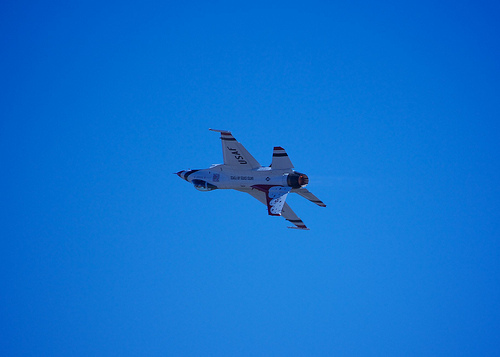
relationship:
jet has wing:
[173, 128, 327, 231] [207, 117, 268, 179]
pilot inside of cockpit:
[198, 177, 205, 193] [192, 172, 217, 198]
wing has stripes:
[207, 117, 268, 179] [206, 114, 247, 150]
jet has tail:
[161, 102, 335, 252] [267, 135, 338, 217]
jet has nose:
[161, 102, 335, 252] [152, 159, 196, 191]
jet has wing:
[161, 102, 335, 252] [207, 117, 268, 179]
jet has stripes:
[161, 102, 335, 252] [206, 114, 247, 150]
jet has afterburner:
[161, 102, 335, 252] [285, 155, 310, 191]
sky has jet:
[184, 27, 271, 74] [161, 102, 335, 252]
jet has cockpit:
[161, 102, 335, 252] [192, 172, 217, 198]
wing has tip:
[207, 117, 268, 179] [219, 128, 233, 139]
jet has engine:
[161, 102, 335, 252] [290, 177, 300, 195]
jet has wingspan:
[161, 102, 335, 252] [210, 110, 267, 251]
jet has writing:
[161, 102, 335, 252] [230, 167, 261, 187]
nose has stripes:
[152, 159, 196, 191] [206, 114, 247, 150]